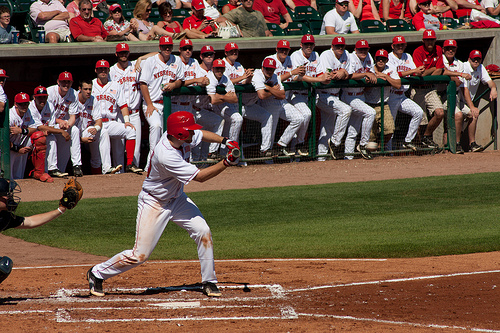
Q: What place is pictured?
A: It is a field.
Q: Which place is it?
A: It is a field.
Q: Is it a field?
A: Yes, it is a field.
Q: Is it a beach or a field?
A: It is a field.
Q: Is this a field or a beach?
A: It is a field.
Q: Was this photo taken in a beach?
A: No, the picture was taken in a field.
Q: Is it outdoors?
A: Yes, it is outdoors.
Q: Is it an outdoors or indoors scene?
A: It is outdoors.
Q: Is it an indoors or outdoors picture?
A: It is outdoors.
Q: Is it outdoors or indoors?
A: It is outdoors.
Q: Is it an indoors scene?
A: No, it is outdoors.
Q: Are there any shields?
A: No, there are no shields.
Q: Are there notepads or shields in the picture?
A: No, there are no shields or notepads.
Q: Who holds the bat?
A: The batter holds the bat.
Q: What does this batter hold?
A: The batter holds the bat.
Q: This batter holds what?
A: The batter holds the bat.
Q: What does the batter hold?
A: The batter holds the bat.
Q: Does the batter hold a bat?
A: Yes, the batter holds a bat.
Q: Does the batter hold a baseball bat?
A: No, the batter holds a bat.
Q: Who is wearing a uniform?
A: The batter is wearing a uniform.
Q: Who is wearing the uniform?
A: The batter is wearing a uniform.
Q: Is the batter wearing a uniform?
A: Yes, the batter is wearing a uniform.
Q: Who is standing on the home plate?
A: The batter is standing on the home plate.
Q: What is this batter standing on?
A: The batter is standing on the home plate.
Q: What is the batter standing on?
A: The batter is standing on the home plate.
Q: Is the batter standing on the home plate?
A: Yes, the batter is standing on the home plate.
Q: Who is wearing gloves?
A: The batter is wearing gloves.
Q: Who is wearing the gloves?
A: The batter is wearing gloves.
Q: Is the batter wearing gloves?
A: Yes, the batter is wearing gloves.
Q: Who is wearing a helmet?
A: The batter is wearing a helmet.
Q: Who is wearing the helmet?
A: The batter is wearing a helmet.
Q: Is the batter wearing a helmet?
A: Yes, the batter is wearing a helmet.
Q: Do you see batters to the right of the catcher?
A: Yes, there is a batter to the right of the catcher.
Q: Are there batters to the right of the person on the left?
A: Yes, there is a batter to the right of the catcher.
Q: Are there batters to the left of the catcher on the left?
A: No, the batter is to the right of the catcher.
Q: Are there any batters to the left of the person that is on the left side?
A: No, the batter is to the right of the catcher.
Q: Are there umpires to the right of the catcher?
A: No, there is a batter to the right of the catcher.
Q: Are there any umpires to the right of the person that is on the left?
A: No, there is a batter to the right of the catcher.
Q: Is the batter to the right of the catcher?
A: Yes, the batter is to the right of the catcher.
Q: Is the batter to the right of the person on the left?
A: Yes, the batter is to the right of the catcher.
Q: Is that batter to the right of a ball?
A: No, the batter is to the right of the catcher.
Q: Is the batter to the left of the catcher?
A: No, the batter is to the right of the catcher.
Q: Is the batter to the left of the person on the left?
A: No, the batter is to the right of the catcher.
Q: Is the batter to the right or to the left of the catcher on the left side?
A: The batter is to the right of the catcher.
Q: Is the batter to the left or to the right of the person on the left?
A: The batter is to the right of the catcher.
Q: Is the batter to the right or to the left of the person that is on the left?
A: The batter is to the right of the catcher.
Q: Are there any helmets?
A: Yes, there is a helmet.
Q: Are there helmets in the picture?
A: Yes, there is a helmet.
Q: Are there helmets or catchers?
A: Yes, there is a helmet.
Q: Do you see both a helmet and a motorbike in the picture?
A: No, there is a helmet but no motorcycles.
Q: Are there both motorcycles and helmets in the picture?
A: No, there is a helmet but no motorcycles.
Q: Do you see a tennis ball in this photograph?
A: No, there are no tennis balls.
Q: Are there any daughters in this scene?
A: No, there are no daughters.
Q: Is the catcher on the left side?
A: Yes, the catcher is on the left of the image.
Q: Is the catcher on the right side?
A: No, the catcher is on the left of the image.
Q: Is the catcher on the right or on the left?
A: The catcher is on the left of the image.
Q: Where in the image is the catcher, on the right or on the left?
A: The catcher is on the left of the image.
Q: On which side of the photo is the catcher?
A: The catcher is on the left of the image.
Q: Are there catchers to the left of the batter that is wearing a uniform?
A: Yes, there is a catcher to the left of the batter.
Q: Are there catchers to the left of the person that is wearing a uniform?
A: Yes, there is a catcher to the left of the batter.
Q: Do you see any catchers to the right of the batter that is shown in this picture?
A: No, the catcher is to the left of the batter.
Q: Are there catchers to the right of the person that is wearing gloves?
A: No, the catcher is to the left of the batter.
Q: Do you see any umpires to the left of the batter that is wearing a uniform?
A: No, there is a catcher to the left of the batter.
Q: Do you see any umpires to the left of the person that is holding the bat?
A: No, there is a catcher to the left of the batter.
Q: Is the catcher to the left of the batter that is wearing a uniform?
A: Yes, the catcher is to the left of the batter.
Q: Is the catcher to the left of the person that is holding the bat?
A: Yes, the catcher is to the left of the batter.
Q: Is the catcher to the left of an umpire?
A: No, the catcher is to the left of the batter.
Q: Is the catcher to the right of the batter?
A: No, the catcher is to the left of the batter.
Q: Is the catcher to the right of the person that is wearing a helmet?
A: No, the catcher is to the left of the batter.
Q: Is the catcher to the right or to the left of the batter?
A: The catcher is to the left of the batter.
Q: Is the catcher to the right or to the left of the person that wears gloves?
A: The catcher is to the left of the batter.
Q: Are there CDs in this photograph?
A: No, there are no cds.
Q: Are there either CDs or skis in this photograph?
A: No, there are no CDs or skis.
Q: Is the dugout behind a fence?
A: Yes, the dugout is behind a fence.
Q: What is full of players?
A: The dugout is full of players.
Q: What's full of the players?
A: The dugout is full of players.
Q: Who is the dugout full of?
A: The dugout is full of players.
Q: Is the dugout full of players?
A: Yes, the dugout is full of players.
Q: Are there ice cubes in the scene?
A: No, there are no ice cubes.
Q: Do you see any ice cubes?
A: No, there are no ice cubes.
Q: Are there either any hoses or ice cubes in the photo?
A: No, there are no ice cubes or hoses.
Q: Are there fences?
A: Yes, there is a fence.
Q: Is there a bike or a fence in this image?
A: Yes, there is a fence.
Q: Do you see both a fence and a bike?
A: No, there is a fence but no bikes.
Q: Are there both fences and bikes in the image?
A: No, there is a fence but no bikes.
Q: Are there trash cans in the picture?
A: No, there are no trash cans.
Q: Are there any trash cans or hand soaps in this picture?
A: No, there are no trash cans or hand soaps.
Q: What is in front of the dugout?
A: The fence is in front of the dugout.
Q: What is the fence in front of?
A: The fence is in front of the dugout.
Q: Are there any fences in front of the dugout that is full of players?
A: Yes, there is a fence in front of the dugout.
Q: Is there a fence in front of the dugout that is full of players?
A: Yes, there is a fence in front of the dugout.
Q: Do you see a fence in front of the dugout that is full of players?
A: Yes, there is a fence in front of the dugout.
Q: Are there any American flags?
A: No, there are no American flags.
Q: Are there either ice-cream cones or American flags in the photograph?
A: No, there are no American flags or ice-cream cones.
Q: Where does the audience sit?
A: The audience sits in the bleachers.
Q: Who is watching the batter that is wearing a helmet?
A: The audience is watching the batter.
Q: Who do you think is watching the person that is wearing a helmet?
A: The audience is watching the batter.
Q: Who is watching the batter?
A: The audience is watching the batter.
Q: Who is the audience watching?
A: The audience is watching the batter.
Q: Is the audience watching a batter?
A: Yes, the audience is watching a batter.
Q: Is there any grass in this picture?
A: Yes, there is grass.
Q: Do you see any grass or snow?
A: Yes, there is grass.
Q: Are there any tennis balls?
A: No, there are no tennis balls.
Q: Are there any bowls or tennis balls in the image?
A: No, there are no tennis balls or bowls.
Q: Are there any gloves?
A: Yes, there are gloves.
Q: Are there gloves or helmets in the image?
A: Yes, there are gloves.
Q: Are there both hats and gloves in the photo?
A: Yes, there are both gloves and a hat.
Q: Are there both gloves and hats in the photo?
A: Yes, there are both gloves and a hat.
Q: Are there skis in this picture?
A: No, there are no skis.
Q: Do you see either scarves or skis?
A: No, there are no skis or scarves.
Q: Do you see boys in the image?
A: No, there are no boys.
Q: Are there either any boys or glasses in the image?
A: No, there are no boys or glasses.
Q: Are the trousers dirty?
A: Yes, the trousers are dirty.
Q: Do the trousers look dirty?
A: Yes, the trousers are dirty.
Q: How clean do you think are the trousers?
A: The trousers are dirty.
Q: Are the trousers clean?
A: No, the trousers are dirty.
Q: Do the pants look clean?
A: No, the pants are dirty.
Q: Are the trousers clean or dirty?
A: The trousers are dirty.